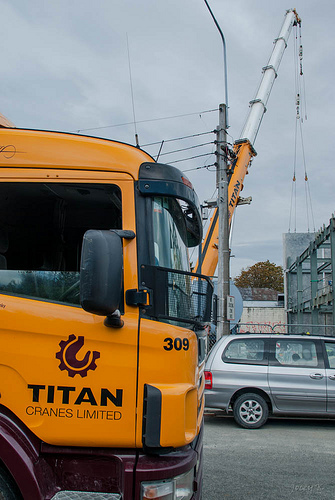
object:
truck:
[0, 127, 212, 499]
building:
[286, 213, 334, 335]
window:
[147, 198, 198, 318]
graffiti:
[237, 321, 288, 333]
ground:
[272, 424, 285, 460]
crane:
[190, 9, 299, 283]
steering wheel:
[58, 279, 80, 301]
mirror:
[79, 229, 123, 316]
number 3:
[163, 337, 173, 351]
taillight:
[204, 368, 214, 390]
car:
[204, 333, 335, 428]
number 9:
[183, 338, 190, 351]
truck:
[0, 115, 205, 498]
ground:
[172, 24, 215, 48]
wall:
[204, 108, 263, 136]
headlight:
[141, 468, 193, 499]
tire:
[233, 393, 268, 428]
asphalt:
[202, 416, 335, 499]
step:
[45, 456, 132, 500]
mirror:
[80, 225, 123, 316]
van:
[211, 331, 322, 419]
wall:
[231, 320, 285, 334]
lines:
[73, 106, 218, 172]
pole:
[217, 101, 230, 337]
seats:
[290, 342, 313, 363]